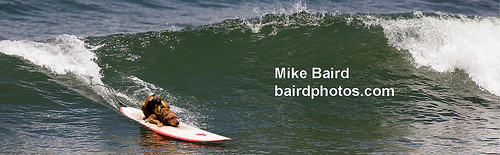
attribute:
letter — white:
[265, 62, 289, 87]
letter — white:
[286, 63, 299, 76]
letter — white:
[307, 59, 325, 77]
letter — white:
[344, 59, 359, 88]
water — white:
[94, 10, 498, 111]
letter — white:
[310, 67, 322, 82]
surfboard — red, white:
[117, 105, 229, 142]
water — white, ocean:
[14, 9, 495, 154]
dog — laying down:
[140, 94, 180, 128]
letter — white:
[323, 69, 330, 79]